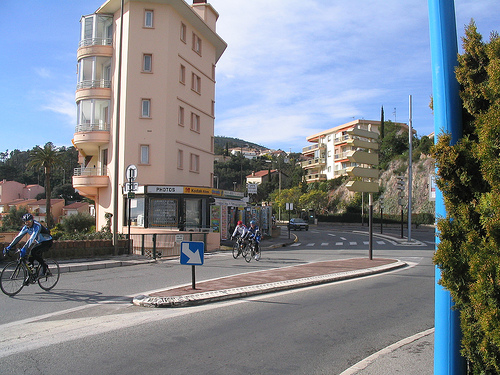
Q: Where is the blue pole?
A: On the right side of the street.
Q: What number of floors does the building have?
A: 5.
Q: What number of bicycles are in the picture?
A: 3.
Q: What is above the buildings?
A: Sky.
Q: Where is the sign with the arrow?
A: In the street island.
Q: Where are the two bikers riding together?
A: In front of the pink building.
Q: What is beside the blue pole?
A: Bushes.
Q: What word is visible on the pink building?
A: Photos.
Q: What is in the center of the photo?
A: A brick median.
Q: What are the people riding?
A: Bicycles.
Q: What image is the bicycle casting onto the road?
A: A shadow.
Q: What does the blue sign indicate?
A: To ride to the right of the median.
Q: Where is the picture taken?
A: On the street.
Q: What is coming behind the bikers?
A: A car.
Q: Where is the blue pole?
A: Near the tree.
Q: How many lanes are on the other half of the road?
A: Two.